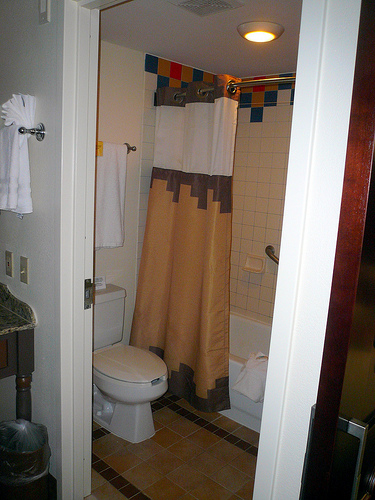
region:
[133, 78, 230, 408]
a shower curtain in the bathroom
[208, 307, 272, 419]
a white bathtub in the bathroom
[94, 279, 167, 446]
a toilet in the bathroom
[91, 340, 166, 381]
a toilet seat on the toilet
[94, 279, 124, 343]
a water closet of the toilet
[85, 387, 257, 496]
brown and beige tile on the bathroom floor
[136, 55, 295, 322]
tile surrounds the bathtub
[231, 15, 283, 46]
a light fixture on the ceiling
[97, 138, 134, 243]
a white towel hanging from a towel rack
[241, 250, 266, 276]
a soap dish on the wall over the bathtub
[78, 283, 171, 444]
A white toilet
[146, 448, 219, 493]
A yellow tiled floor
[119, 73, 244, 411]
a gold and brown shower curtain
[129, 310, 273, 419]
a white tub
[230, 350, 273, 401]
a white wash rag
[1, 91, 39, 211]
a white towel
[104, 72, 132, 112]
a white wall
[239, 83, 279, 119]
yellow, red and blue tile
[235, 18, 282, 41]
a round light on ceiling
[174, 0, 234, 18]
a square vent on ceiling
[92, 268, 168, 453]
white toilet in bathroom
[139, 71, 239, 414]
brown and white shower curtain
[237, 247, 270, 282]
empty soap dish on wall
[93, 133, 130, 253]
towel hanging over toilet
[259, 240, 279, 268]
grab bar over bath tub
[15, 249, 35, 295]
light switch on wall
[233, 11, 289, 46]
light on over tub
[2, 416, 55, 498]
plastic bag in can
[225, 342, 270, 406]
towel on edge of tub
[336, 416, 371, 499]
long silver door knob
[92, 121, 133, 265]
white towel on towel rack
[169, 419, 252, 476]
brown border on tan tile floor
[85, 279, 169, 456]
a white closed lid toilet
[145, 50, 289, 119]
a colorful tile border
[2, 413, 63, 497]
a small brown trash can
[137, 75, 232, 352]
a shower curtain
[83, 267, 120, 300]
a sign atop the toilet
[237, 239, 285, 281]
a in wall soap dish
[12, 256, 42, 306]
a light switch on the wall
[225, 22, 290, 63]
a light fixture in the ceiling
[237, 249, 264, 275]
bath tub soap dish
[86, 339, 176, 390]
bathroom toilet seat lid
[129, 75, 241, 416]
bath tub shower curtain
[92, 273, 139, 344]
bathroom toilet tank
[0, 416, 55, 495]
empty trash can with liner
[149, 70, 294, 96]
bath tub shower curtain rod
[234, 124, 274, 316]
white bath tub tile wall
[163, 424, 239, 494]
brown bathroom tile floor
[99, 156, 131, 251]
white bath towel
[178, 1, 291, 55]
bathroom light and vent